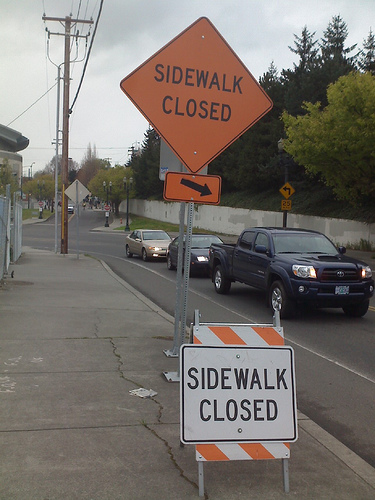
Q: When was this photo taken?
A: During the daytime.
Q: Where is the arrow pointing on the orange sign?
A: To the right.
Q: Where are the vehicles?
A: On the street.